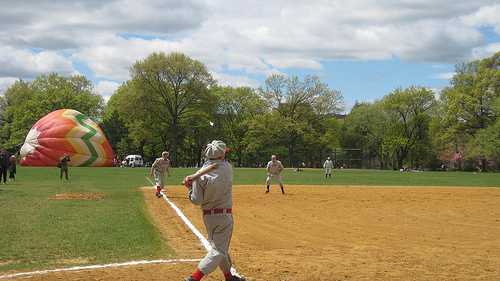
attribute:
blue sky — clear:
[319, 57, 451, 109]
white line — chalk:
[147, 177, 240, 279]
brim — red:
[223, 148, 230, 153]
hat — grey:
[205, 139, 231, 156]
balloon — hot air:
[18, 105, 115, 167]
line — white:
[155, 182, 210, 272]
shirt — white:
[264, 162, 284, 174]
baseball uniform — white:
[183, 161, 253, 276]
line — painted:
[148, 171, 238, 276]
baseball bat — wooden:
[179, 167, 230, 187]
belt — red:
[199, 204, 232, 213]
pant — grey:
[196, 214, 265, 279]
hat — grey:
[189, 138, 256, 171]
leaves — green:
[183, 98, 211, 112]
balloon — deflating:
[15, 104, 116, 171]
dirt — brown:
[349, 220, 461, 262]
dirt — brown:
[2, 182, 498, 279]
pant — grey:
[151, 170, 163, 186]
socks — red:
[181, 256, 238, 275]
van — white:
[119, 147, 147, 167]